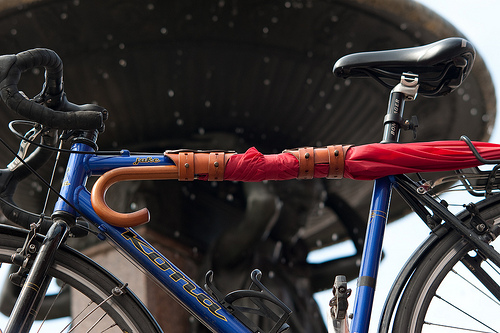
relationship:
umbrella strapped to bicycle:
[84, 135, 499, 233] [1, 31, 493, 331]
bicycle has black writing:
[1, 31, 493, 331] [122, 227, 233, 325]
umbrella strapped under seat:
[84, 135, 499, 233] [326, 34, 482, 105]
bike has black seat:
[1, 31, 493, 331] [326, 34, 482, 105]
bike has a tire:
[1, 31, 493, 331] [2, 219, 166, 332]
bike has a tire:
[1, 31, 493, 331] [370, 190, 499, 333]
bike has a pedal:
[1, 31, 493, 331] [326, 270, 353, 322]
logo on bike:
[122, 227, 233, 325] [1, 31, 493, 331]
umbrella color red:
[84, 135, 499, 233] [201, 135, 498, 188]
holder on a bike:
[203, 264, 302, 332] [1, 31, 493, 331]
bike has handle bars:
[1, 31, 493, 331] [2, 39, 100, 184]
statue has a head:
[207, 125, 331, 332] [264, 169, 330, 256]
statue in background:
[207, 125, 331, 332] [166, 180, 362, 261]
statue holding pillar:
[207, 125, 331, 332] [5, 3, 498, 121]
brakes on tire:
[461, 201, 499, 252] [370, 190, 499, 333]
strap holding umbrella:
[177, 141, 346, 187] [84, 135, 499, 233]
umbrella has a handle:
[84, 135, 499, 233] [88, 161, 177, 234]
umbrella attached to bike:
[84, 135, 499, 233] [1, 31, 493, 331]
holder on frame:
[203, 264, 302, 332] [60, 135, 403, 332]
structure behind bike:
[5, 3, 498, 121] [1, 31, 493, 331]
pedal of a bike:
[326, 270, 353, 322] [1, 31, 493, 331]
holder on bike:
[203, 264, 302, 332] [1, 31, 493, 331]